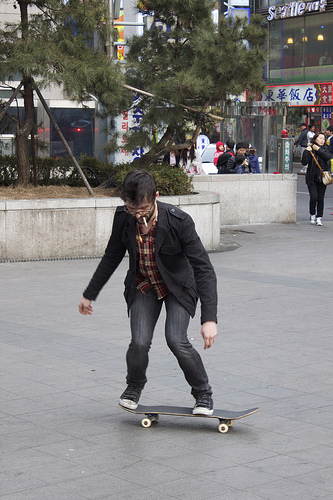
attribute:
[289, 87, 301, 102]
word — blue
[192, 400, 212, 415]
shoe — black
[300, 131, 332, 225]
women — Asian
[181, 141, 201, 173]
women — Asian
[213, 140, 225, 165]
coat — pink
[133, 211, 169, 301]
shirt — red, plaid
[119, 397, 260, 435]
skateboard — black, white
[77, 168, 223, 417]
man — white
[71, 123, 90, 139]
light — red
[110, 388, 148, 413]
shoe — black, white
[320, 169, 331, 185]
bag — brown, white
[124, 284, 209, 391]
jeans — dark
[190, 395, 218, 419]
shoe — white, black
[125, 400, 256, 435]
skateboard — black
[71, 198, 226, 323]
coat — black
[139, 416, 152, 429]
wheel — white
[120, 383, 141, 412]
shoe — black